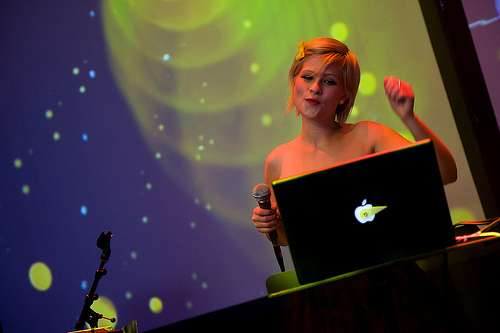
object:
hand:
[383, 75, 415, 120]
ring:
[399, 79, 401, 88]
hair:
[284, 37, 360, 127]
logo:
[354, 199, 388, 224]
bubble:
[72, 67, 80, 75]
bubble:
[29, 261, 53, 291]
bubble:
[81, 133, 88, 141]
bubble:
[53, 132, 60, 142]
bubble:
[80, 205, 88, 216]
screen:
[0, 0, 496, 333]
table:
[134, 231, 499, 333]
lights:
[1, 0, 492, 332]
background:
[0, 0, 487, 333]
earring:
[340, 100, 343, 104]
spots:
[28, 261, 52, 291]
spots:
[80, 205, 87, 217]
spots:
[81, 133, 89, 141]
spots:
[45, 109, 54, 119]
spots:
[145, 182, 152, 190]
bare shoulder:
[264, 144, 283, 187]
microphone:
[251, 183, 285, 272]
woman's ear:
[338, 96, 348, 105]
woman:
[251, 38, 457, 247]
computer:
[273, 138, 457, 284]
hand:
[251, 203, 280, 233]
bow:
[296, 40, 306, 60]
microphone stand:
[77, 230, 121, 333]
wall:
[0, 0, 495, 333]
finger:
[383, 75, 412, 104]